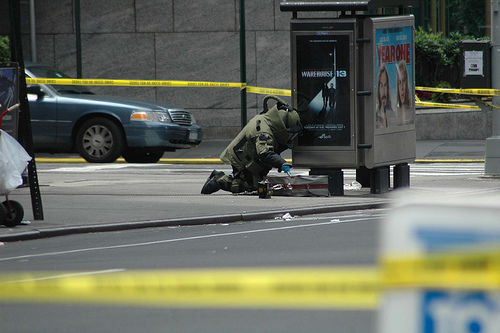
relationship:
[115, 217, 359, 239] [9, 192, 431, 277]
line in road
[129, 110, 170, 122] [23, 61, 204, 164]
headlight on car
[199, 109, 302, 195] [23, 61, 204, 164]
man sitting near car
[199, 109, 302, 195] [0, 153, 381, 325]
man kneeling on floor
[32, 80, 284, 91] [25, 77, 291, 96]
black letters on ribbon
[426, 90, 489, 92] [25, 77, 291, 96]
black letters on ribbon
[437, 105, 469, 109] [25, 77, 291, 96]
black letters on ribbon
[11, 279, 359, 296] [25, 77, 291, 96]
black letters on ribbon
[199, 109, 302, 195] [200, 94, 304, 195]
man in clothes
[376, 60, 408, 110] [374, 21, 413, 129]
people on ads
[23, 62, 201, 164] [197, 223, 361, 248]
car parked on road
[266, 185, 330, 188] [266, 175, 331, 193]
red line on package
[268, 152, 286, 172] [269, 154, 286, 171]
glove on hand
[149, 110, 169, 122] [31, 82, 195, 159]
headlight on car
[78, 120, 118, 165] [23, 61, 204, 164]
tire on car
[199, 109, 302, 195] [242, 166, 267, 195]
man down on knees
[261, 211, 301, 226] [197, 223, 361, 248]
litter on road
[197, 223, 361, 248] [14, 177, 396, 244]
road near curb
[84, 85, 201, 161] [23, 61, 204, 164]
front end of car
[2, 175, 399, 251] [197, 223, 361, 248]
curb beside road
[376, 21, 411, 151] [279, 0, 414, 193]
ads on kiosk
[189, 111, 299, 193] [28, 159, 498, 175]
man sitting in road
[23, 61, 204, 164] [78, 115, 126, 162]
car has tire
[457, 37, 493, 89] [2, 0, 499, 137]
board in building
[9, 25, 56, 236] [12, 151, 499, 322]
iron rod in road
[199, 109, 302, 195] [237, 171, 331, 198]
man diffusing bomb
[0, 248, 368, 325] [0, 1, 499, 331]
floor in area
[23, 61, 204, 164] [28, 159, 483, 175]
car parked on side of road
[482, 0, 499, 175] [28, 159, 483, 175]
utility pole on road